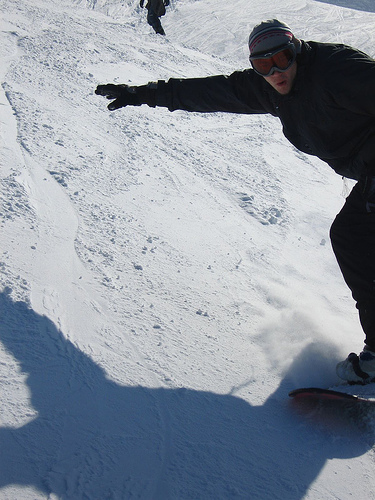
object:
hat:
[248, 18, 295, 56]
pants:
[328, 177, 375, 353]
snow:
[251, 280, 346, 381]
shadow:
[0, 284, 373, 500]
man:
[138, 0, 172, 36]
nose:
[271, 69, 283, 78]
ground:
[249, 241, 283, 343]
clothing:
[146, 38, 375, 350]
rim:
[288, 385, 375, 405]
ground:
[25, 18, 331, 294]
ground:
[327, 100, 350, 127]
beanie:
[247, 27, 294, 62]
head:
[247, 18, 301, 96]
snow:
[285, 348, 373, 409]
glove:
[94, 81, 156, 112]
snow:
[0, 3, 375, 499]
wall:
[151, 68, 265, 116]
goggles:
[249, 40, 297, 78]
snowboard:
[288, 380, 374, 402]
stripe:
[249, 28, 293, 53]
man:
[94, 16, 374, 386]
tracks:
[149, 194, 288, 331]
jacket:
[156, 38, 374, 184]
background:
[0, 0, 375, 500]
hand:
[94, 83, 145, 111]